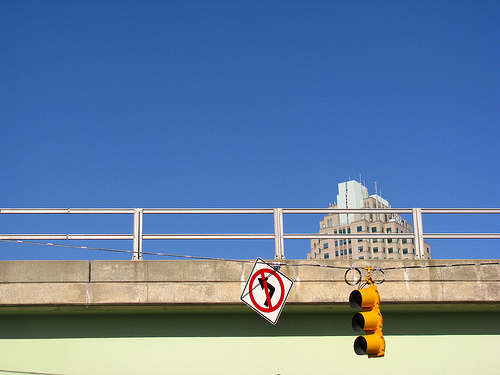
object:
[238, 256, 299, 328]
sign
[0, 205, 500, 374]
bridge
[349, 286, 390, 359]
traffic light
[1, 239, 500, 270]
wire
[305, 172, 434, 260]
building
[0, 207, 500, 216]
railing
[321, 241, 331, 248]
window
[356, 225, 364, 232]
window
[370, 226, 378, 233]
window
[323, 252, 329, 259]
window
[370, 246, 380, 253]
window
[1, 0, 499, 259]
sky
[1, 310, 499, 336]
shadow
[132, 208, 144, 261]
post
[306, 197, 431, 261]
lot of windows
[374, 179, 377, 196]
pole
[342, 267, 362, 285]
wire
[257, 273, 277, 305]
arrow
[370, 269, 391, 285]
wire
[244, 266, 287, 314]
circle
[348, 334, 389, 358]
bottom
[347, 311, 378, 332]
middle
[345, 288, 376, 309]
top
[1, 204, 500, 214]
horizontal bar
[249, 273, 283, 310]
no left turn